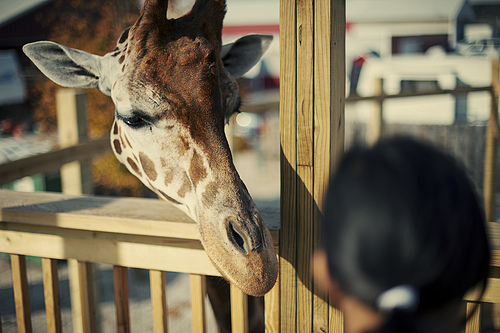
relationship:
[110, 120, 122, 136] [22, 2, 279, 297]
spot on giraffe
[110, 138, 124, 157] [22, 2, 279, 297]
spot on giraffe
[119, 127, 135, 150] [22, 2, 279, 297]
spot on giraffe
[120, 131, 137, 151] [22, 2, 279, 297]
spot on giraffe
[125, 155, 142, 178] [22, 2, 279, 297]
spot on giraffe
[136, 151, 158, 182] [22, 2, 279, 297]
brown spot on giraffe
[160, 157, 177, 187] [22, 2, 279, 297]
brown spot on giraffe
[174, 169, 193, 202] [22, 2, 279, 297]
spot on giraffe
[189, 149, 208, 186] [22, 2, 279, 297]
brown spot on giraffe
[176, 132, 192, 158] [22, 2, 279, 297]
spot on giraffe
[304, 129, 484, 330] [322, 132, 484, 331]
person has black hair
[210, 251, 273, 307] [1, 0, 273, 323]
mouth of giraffe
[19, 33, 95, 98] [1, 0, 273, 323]
ear of giraffe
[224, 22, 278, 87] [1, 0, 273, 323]
ear of giraffe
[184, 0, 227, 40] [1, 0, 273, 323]
horn of giraffe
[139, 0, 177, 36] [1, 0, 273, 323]
horn of giraffe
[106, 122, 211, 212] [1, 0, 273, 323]
spots on giraffe